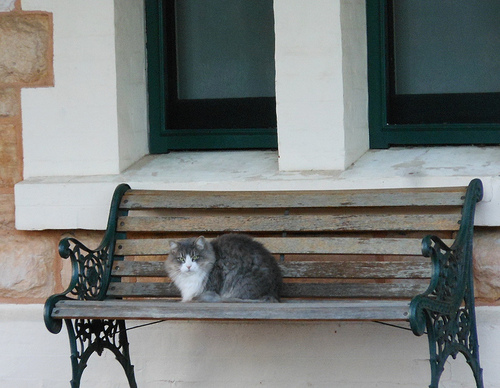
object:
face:
[171, 246, 205, 275]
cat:
[163, 233, 282, 304]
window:
[363, 1, 499, 151]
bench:
[43, 177, 484, 384]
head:
[167, 235, 207, 275]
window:
[142, 0, 276, 156]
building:
[0, 1, 499, 387]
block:
[0, 233, 61, 306]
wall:
[4, 3, 494, 388]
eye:
[177, 254, 201, 262]